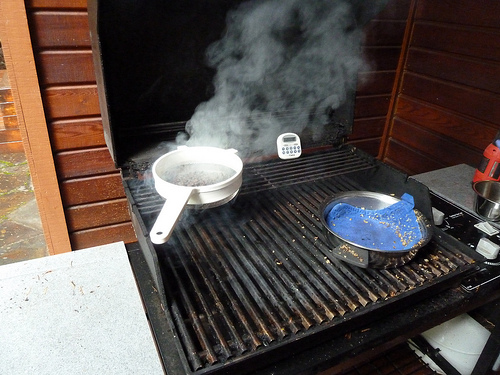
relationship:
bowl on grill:
[141, 129, 255, 257] [123, 120, 498, 368]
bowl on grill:
[316, 190, 438, 270] [90, 115, 490, 367]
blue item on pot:
[327, 194, 424, 255] [321, 183, 446, 291]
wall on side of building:
[0, 0, 499, 252] [3, 6, 491, 251]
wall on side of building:
[22, 155, 155, 280] [3, 6, 491, 251]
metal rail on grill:
[163, 246, 244, 359] [125, 145, 495, 373]